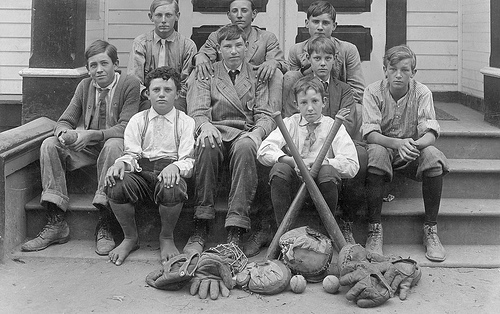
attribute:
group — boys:
[17, 0, 449, 269]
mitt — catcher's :
[191, 255, 235, 300]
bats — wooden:
[274, 110, 358, 273]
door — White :
[174, 0, 429, 80]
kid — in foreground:
[103, 62, 199, 266]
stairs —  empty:
[447, 117, 499, 266]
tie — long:
[92, 86, 111, 128]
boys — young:
[18, 0, 454, 269]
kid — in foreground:
[356, 40, 451, 265]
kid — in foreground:
[259, 85, 361, 242]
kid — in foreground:
[189, 27, 287, 249]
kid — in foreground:
[10, 27, 150, 257]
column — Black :
[8, 8, 107, 160]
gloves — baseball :
[147, 252, 232, 297]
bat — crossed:
[271, 107, 346, 253]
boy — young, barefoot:
[91, 62, 238, 272]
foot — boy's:
[158, 232, 180, 264]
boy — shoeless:
[107, 67, 200, 267]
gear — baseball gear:
[152, 220, 429, 311]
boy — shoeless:
[98, 64, 203, 270]